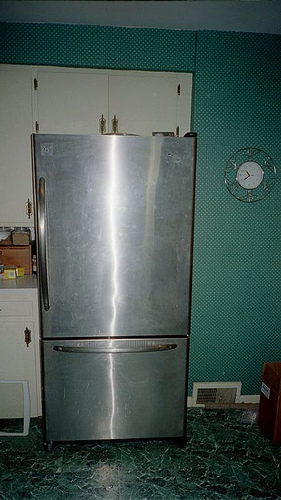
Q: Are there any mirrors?
A: No, there are no mirrors.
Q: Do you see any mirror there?
A: No, there are no mirrors.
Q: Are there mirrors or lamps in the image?
A: No, there are no mirrors or lamps.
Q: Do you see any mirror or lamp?
A: No, there are no mirrors or lamps.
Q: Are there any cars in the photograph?
A: No, there are no cars.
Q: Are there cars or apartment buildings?
A: No, there are no cars or apartment buildings.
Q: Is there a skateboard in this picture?
A: No, there are no skateboards.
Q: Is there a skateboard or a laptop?
A: No, there are no skateboards or laptops.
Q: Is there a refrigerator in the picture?
A: Yes, there is a refrigerator.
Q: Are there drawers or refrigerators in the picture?
A: Yes, there is a refrigerator.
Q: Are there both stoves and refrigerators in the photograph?
A: No, there is a refrigerator but no stoves.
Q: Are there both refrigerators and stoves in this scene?
A: No, there is a refrigerator but no stoves.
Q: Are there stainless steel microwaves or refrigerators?
A: Yes, there is a stainless steel refrigerator.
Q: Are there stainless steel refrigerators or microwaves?
A: Yes, there is a stainless steel refrigerator.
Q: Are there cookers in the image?
A: No, there are no cookers.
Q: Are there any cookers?
A: No, there are no cookers.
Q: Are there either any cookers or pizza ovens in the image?
A: No, there are no cookers or pizza ovens.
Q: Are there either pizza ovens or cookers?
A: No, there are no cookers or pizza ovens.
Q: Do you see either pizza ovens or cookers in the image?
A: No, there are no cookers or pizza ovens.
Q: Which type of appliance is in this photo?
A: The appliance is a refrigerator.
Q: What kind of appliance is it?
A: The appliance is a refrigerator.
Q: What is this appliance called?
A: This is a refrigerator.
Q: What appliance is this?
A: This is a refrigerator.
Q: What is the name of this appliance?
A: This is a refrigerator.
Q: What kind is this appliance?
A: This is a refrigerator.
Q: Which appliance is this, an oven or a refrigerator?
A: This is a refrigerator.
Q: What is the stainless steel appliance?
A: The appliance is a refrigerator.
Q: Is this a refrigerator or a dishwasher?
A: This is a refrigerator.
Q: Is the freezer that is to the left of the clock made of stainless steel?
A: Yes, the refrigerator is made of stainless steel.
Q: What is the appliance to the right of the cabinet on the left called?
A: The appliance is a refrigerator.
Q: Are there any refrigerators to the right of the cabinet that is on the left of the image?
A: Yes, there is a refrigerator to the right of the cabinet.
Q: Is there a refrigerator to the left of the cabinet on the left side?
A: No, the refrigerator is to the right of the cabinet.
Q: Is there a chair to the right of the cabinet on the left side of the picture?
A: No, there is a refrigerator to the right of the cabinet.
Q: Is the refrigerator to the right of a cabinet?
A: Yes, the refrigerator is to the right of a cabinet.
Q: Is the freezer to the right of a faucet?
A: No, the freezer is to the right of a cabinet.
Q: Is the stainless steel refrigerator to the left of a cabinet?
A: No, the freezer is to the right of a cabinet.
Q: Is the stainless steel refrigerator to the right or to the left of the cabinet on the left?
A: The freezer is to the right of the cabinet.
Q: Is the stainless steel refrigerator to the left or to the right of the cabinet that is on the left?
A: The freezer is to the right of the cabinet.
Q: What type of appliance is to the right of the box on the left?
A: The appliance is a refrigerator.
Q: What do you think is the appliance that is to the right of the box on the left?
A: The appliance is a refrigerator.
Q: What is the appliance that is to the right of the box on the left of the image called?
A: The appliance is a refrigerator.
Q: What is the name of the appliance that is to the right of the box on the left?
A: The appliance is a refrigerator.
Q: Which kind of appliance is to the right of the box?
A: The appliance is a refrigerator.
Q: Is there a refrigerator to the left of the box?
A: No, the refrigerator is to the right of the box.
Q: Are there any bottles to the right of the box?
A: No, there is a refrigerator to the right of the box.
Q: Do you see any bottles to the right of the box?
A: No, there is a refrigerator to the right of the box.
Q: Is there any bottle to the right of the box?
A: No, there is a refrigerator to the right of the box.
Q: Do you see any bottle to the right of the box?
A: No, there is a refrigerator to the right of the box.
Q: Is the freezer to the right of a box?
A: Yes, the freezer is to the right of a box.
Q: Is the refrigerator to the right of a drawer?
A: No, the refrigerator is to the right of a box.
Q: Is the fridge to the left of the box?
A: No, the fridge is to the right of the box.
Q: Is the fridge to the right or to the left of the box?
A: The fridge is to the right of the box.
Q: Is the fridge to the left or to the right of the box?
A: The fridge is to the right of the box.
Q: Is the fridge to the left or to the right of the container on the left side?
A: The fridge is to the right of the box.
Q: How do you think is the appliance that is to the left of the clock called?
A: The appliance is a refrigerator.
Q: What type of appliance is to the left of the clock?
A: The appliance is a refrigerator.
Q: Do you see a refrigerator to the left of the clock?
A: Yes, there is a refrigerator to the left of the clock.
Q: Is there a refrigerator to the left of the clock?
A: Yes, there is a refrigerator to the left of the clock.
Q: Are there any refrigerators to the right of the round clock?
A: No, the refrigerator is to the left of the clock.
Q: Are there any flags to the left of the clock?
A: No, there is a refrigerator to the left of the clock.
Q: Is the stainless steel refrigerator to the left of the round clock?
A: Yes, the fridge is to the left of the clock.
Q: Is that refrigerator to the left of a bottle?
A: No, the refrigerator is to the left of the clock.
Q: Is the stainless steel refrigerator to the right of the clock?
A: No, the freezer is to the left of the clock.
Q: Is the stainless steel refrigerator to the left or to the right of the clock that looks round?
A: The freezer is to the left of the clock.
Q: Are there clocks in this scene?
A: Yes, there is a clock.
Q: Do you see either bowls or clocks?
A: Yes, there is a clock.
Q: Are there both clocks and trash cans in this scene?
A: No, there is a clock but no trash cans.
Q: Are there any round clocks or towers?
A: Yes, there is a round clock.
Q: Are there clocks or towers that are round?
A: Yes, the clock is round.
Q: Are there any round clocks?
A: Yes, there is a round clock.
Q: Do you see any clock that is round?
A: Yes, there is a clock that is round.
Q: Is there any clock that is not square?
A: Yes, there is a round clock.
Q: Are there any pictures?
A: No, there are no pictures.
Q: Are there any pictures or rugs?
A: No, there are no pictures or rugs.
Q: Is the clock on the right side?
A: Yes, the clock is on the right of the image.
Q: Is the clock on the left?
A: No, the clock is on the right of the image.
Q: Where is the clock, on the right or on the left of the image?
A: The clock is on the right of the image.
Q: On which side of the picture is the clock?
A: The clock is on the right of the image.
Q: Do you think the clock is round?
A: Yes, the clock is round.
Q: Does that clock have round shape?
A: Yes, the clock is round.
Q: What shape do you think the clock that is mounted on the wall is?
A: The clock is round.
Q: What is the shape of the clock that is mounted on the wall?
A: The clock is round.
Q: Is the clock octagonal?
A: No, the clock is round.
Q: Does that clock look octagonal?
A: No, the clock is round.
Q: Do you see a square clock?
A: No, there is a clock but it is round.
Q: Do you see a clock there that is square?
A: No, there is a clock but it is round.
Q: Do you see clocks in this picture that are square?
A: No, there is a clock but it is round.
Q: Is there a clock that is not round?
A: No, there is a clock but it is round.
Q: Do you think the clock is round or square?
A: The clock is round.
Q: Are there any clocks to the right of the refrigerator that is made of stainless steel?
A: Yes, there is a clock to the right of the freezer.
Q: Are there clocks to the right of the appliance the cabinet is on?
A: Yes, there is a clock to the right of the freezer.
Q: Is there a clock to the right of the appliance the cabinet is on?
A: Yes, there is a clock to the right of the freezer.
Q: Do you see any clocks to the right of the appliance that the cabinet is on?
A: Yes, there is a clock to the right of the freezer.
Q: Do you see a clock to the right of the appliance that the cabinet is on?
A: Yes, there is a clock to the right of the freezer.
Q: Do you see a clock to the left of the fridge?
A: No, the clock is to the right of the fridge.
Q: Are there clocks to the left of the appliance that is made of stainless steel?
A: No, the clock is to the right of the fridge.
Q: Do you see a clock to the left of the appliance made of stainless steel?
A: No, the clock is to the right of the fridge.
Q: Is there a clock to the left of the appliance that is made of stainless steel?
A: No, the clock is to the right of the fridge.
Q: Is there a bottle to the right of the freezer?
A: No, there is a clock to the right of the freezer.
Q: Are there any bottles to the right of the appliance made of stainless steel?
A: No, there is a clock to the right of the freezer.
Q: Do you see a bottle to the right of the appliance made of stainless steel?
A: No, there is a clock to the right of the freezer.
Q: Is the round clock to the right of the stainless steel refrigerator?
A: Yes, the clock is to the right of the freezer.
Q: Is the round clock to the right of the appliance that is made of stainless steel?
A: Yes, the clock is to the right of the freezer.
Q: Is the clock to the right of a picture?
A: No, the clock is to the right of the freezer.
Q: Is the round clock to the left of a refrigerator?
A: No, the clock is to the right of a refrigerator.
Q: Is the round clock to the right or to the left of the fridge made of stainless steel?
A: The clock is to the right of the freezer.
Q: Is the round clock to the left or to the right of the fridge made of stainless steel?
A: The clock is to the right of the freezer.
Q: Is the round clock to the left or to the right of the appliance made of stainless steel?
A: The clock is to the right of the freezer.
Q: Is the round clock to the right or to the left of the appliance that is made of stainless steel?
A: The clock is to the right of the freezer.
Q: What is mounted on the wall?
A: The clock is mounted on the wall.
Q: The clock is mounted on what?
A: The clock is mounted on the wall.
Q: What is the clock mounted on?
A: The clock is mounted on the wall.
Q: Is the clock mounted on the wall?
A: Yes, the clock is mounted on the wall.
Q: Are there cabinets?
A: Yes, there is a cabinet.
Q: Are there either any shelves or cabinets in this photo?
A: Yes, there is a cabinet.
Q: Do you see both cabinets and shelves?
A: No, there is a cabinet but no shelves.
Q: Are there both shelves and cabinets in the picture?
A: No, there is a cabinet but no shelves.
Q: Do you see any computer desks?
A: No, there are no computer desks.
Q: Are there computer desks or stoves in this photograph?
A: No, there are no computer desks or stoves.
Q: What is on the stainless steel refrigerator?
A: The cabinet is on the fridge.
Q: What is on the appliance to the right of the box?
A: The cabinet is on the fridge.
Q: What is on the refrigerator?
A: The cabinet is on the fridge.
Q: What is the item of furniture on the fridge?
A: The piece of furniture is a cabinet.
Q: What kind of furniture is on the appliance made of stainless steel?
A: The piece of furniture is a cabinet.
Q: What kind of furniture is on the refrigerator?
A: The piece of furniture is a cabinet.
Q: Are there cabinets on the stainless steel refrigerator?
A: Yes, there is a cabinet on the freezer.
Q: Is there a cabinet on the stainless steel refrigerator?
A: Yes, there is a cabinet on the freezer.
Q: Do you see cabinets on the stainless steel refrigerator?
A: Yes, there is a cabinet on the freezer.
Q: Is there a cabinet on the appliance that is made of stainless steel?
A: Yes, there is a cabinet on the freezer.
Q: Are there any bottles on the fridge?
A: No, there is a cabinet on the fridge.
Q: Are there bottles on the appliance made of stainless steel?
A: No, there is a cabinet on the fridge.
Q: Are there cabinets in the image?
A: Yes, there is a cabinet.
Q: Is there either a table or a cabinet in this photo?
A: Yes, there is a cabinet.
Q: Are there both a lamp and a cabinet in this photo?
A: No, there is a cabinet but no lamps.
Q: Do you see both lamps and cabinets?
A: No, there is a cabinet but no lamps.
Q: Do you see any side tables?
A: No, there are no side tables.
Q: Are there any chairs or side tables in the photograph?
A: No, there are no side tables or chairs.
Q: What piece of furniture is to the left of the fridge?
A: The piece of furniture is a cabinet.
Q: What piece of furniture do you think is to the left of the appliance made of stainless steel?
A: The piece of furniture is a cabinet.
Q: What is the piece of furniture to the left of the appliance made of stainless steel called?
A: The piece of furniture is a cabinet.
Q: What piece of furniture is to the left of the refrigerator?
A: The piece of furniture is a cabinet.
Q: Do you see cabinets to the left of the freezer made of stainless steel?
A: Yes, there is a cabinet to the left of the freezer.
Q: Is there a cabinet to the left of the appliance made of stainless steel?
A: Yes, there is a cabinet to the left of the freezer.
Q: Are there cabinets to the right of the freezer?
A: No, the cabinet is to the left of the freezer.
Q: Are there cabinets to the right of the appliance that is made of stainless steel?
A: No, the cabinet is to the left of the freezer.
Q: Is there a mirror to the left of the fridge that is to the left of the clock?
A: No, there is a cabinet to the left of the fridge.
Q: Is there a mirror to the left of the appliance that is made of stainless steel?
A: No, there is a cabinet to the left of the fridge.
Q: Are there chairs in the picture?
A: No, there are no chairs.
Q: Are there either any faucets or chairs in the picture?
A: No, there are no chairs or faucets.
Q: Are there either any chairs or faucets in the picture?
A: No, there are no chairs or faucets.